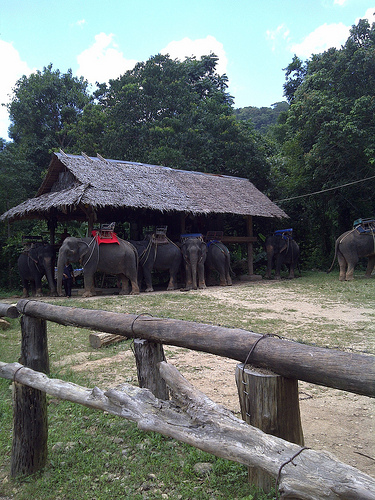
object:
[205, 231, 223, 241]
bench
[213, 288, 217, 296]
dirt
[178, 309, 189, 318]
grass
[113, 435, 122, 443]
rocks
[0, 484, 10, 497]
grass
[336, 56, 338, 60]
bushes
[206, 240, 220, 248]
blankets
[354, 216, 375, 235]
seats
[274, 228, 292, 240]
seats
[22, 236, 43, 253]
seats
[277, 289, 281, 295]
tan dirt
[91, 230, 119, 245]
blanket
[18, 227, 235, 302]
herd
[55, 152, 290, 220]
roof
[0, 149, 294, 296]
barn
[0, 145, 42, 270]
tall trees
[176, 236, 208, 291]
elephant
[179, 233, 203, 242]
seats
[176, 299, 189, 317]
patch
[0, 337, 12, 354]
grass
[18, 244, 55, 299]
elephant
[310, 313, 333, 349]
ground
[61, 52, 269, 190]
tree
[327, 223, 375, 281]
elephant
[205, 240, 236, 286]
elephant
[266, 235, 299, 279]
elephant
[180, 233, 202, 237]
blue seat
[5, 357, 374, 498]
log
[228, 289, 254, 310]
ground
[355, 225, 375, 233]
blanket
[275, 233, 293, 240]
blanket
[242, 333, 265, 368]
wire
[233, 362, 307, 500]
post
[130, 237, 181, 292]
elephant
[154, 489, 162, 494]
pebble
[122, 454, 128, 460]
pebble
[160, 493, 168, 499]
pebble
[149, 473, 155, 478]
pebble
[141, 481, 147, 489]
pebble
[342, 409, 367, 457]
ground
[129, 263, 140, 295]
leg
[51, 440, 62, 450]
pebbles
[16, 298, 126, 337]
brown wood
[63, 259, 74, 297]
person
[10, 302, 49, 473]
post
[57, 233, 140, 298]
elephant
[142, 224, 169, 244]
elephant seat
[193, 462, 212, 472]
rock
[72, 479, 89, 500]
grass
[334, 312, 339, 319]
sand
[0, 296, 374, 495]
fence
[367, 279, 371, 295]
grass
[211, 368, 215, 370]
pebbles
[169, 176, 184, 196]
hay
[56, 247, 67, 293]
trunk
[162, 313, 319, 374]
pole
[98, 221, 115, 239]
seat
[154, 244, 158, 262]
straps